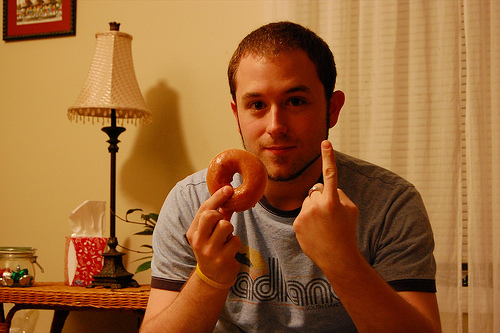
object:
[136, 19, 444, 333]
man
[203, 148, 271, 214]
donut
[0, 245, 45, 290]
jar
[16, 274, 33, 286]
candy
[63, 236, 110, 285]
box of tissue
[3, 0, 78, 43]
picture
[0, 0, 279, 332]
wall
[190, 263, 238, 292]
bracelet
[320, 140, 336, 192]
finger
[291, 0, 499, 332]
curtains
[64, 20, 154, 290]
lamp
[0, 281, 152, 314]
table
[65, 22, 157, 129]
lamp shade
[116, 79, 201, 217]
shadow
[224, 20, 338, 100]
hair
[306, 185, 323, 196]
ring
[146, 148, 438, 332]
shirt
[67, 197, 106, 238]
tissue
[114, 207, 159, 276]
plant